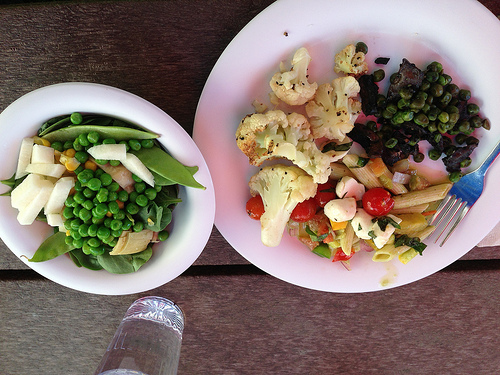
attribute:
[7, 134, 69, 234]
cheese chunks — small, white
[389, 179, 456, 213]
pasta — white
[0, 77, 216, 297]
bowl — white, small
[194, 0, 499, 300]
plate — white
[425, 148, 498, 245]
fork — silver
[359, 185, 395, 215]
tomato — small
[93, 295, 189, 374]
glass — clear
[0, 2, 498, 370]
table — wooden, brown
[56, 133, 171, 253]
peas — green